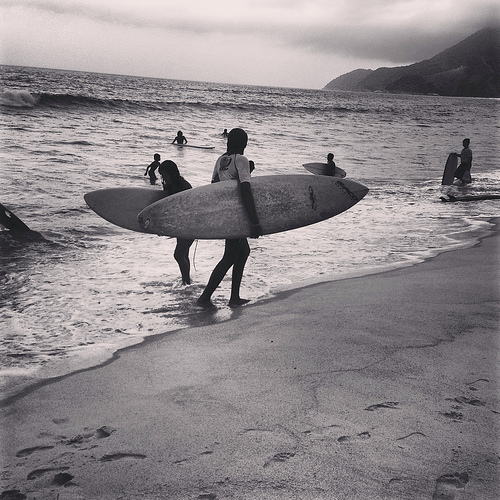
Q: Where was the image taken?
A: It was taken at the ocean.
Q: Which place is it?
A: It is an ocean.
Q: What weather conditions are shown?
A: It is overcast.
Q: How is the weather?
A: It is overcast.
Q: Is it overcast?
A: Yes, it is overcast.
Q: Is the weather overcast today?
A: Yes, it is overcast.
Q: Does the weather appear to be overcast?
A: Yes, it is overcast.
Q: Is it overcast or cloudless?
A: It is overcast.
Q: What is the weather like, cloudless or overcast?
A: It is overcast.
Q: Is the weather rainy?
A: No, it is overcast.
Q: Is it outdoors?
A: Yes, it is outdoors.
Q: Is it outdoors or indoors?
A: It is outdoors.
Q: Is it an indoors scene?
A: No, it is outdoors.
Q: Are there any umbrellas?
A: No, there are no umbrellas.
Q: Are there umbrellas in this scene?
A: No, there are no umbrellas.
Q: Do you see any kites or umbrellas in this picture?
A: No, there are no umbrellas or kites.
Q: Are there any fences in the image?
A: No, there are no fences.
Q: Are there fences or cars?
A: No, there are no fences or cars.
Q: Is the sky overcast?
A: Yes, the sky is overcast.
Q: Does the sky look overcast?
A: Yes, the sky is overcast.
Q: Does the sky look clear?
A: No, the sky is overcast.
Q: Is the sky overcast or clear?
A: The sky is overcast.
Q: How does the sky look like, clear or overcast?
A: The sky is overcast.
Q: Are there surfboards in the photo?
A: Yes, there is a surfboard.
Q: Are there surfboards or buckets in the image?
A: Yes, there is a surfboard.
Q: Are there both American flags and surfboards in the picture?
A: No, there is a surfboard but no American flags.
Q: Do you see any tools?
A: No, there are no tools.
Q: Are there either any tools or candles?
A: No, there are no tools or candles.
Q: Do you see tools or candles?
A: No, there are no tools or candles.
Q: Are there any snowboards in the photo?
A: No, there are no snowboards.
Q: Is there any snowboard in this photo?
A: No, there are no snowboards.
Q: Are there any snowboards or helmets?
A: No, there are no snowboards or helmets.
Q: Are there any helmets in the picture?
A: No, there are no helmets.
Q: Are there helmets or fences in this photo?
A: No, there are no helmets or fences.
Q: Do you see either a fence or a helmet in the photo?
A: No, there are no helmets or fences.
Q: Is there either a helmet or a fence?
A: No, there are no helmets or fences.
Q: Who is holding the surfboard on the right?
A: The man is holding the surf board.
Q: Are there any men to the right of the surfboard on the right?
A: Yes, there is a man to the right of the surfboard.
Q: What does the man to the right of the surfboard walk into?
A: The man walks into the ocean.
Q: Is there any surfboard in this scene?
A: Yes, there is a surfboard.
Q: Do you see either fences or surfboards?
A: Yes, there is a surfboard.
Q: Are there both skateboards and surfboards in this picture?
A: No, there is a surfboard but no skateboards.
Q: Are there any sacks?
A: No, there are no sacks.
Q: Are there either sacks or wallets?
A: No, there are no sacks or wallets.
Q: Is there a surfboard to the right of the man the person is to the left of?
A: Yes, there is a surfboard to the right of the man.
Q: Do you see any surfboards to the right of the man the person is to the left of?
A: Yes, there is a surfboard to the right of the man.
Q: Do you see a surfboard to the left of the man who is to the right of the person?
A: No, the surfboard is to the right of the man.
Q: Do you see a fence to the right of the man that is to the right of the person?
A: No, there is a surfboard to the right of the man.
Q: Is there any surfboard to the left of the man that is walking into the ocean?
A: Yes, there is a surfboard to the left of the man.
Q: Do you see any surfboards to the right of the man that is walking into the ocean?
A: No, the surfboard is to the left of the man.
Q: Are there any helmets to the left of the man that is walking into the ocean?
A: No, there is a surfboard to the left of the man.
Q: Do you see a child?
A: Yes, there is a child.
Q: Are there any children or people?
A: Yes, there is a child.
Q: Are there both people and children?
A: Yes, there are both a child and a person.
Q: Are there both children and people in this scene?
A: Yes, there are both a child and a person.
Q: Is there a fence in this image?
A: No, there are no fences.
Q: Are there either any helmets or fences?
A: No, there are no fences or helmets.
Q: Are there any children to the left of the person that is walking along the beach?
A: Yes, there is a child to the left of the person.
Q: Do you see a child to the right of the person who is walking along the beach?
A: No, the child is to the left of the person.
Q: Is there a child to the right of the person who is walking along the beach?
A: No, the child is to the left of the person.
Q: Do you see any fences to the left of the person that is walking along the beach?
A: No, there is a child to the left of the person.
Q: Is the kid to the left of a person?
A: Yes, the kid is to the left of a person.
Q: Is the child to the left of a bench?
A: No, the child is to the left of a person.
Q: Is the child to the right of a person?
A: No, the child is to the left of a person.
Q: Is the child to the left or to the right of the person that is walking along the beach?
A: The child is to the left of the person.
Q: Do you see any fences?
A: No, there are no fences.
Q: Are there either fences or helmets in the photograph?
A: No, there are no fences or helmets.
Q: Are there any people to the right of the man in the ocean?
A: Yes, there is a person to the right of the man.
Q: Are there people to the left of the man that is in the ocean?
A: No, the person is to the right of the man.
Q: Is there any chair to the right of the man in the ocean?
A: No, there is a person to the right of the man.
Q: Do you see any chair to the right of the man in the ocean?
A: No, there is a person to the right of the man.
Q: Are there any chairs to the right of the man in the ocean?
A: No, there is a person to the right of the man.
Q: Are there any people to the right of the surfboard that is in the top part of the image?
A: Yes, there is a person to the right of the surf board.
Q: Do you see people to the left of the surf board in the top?
A: No, the person is to the right of the surfboard.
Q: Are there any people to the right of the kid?
A: Yes, there is a person to the right of the kid.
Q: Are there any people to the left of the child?
A: No, the person is to the right of the child.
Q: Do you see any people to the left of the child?
A: No, the person is to the right of the child.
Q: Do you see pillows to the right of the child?
A: No, there is a person to the right of the child.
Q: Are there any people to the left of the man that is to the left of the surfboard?
A: Yes, there is a person to the left of the man.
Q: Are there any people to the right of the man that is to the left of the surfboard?
A: No, the person is to the left of the man.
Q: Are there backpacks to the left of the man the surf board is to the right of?
A: No, there is a person to the left of the man.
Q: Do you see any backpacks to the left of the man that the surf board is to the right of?
A: No, there is a person to the left of the man.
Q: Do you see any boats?
A: No, there are no boats.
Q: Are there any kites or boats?
A: No, there are no boats or kites.